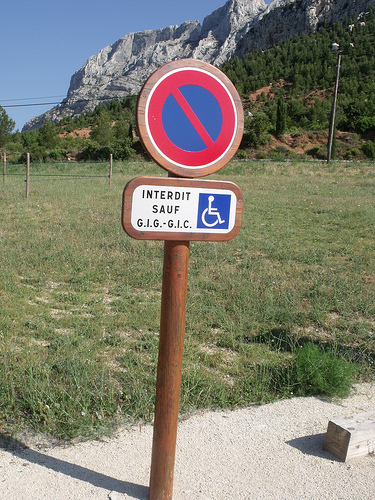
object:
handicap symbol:
[197, 193, 232, 230]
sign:
[122, 176, 243, 241]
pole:
[148, 171, 190, 500]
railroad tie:
[324, 413, 375, 462]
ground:
[211, 387, 373, 499]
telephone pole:
[327, 54, 341, 163]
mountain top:
[67, 0, 265, 96]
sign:
[137, 58, 244, 177]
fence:
[0, 152, 113, 198]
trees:
[276, 96, 286, 135]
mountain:
[21, 1, 375, 135]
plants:
[281, 343, 350, 395]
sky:
[0, 0, 272, 134]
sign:
[121, 58, 244, 500]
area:
[249, 79, 293, 104]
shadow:
[0, 433, 152, 500]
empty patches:
[34, 278, 131, 373]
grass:
[0, 158, 375, 446]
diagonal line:
[171, 87, 214, 148]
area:
[4, 0, 373, 158]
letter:
[137, 219, 143, 227]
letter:
[147, 218, 150, 226]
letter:
[147, 190, 153, 199]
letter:
[184, 220, 189, 228]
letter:
[153, 205, 159, 213]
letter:
[160, 205, 165, 213]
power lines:
[0, 62, 339, 108]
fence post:
[25, 152, 29, 199]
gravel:
[0, 383, 375, 500]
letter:
[175, 206, 180, 214]